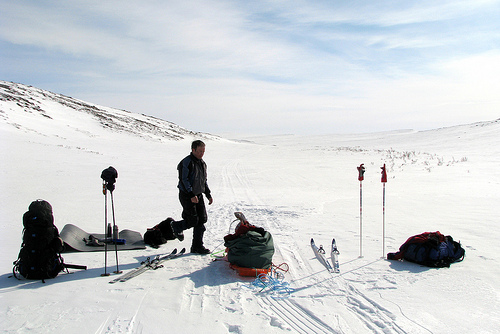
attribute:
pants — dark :
[146, 195, 208, 255]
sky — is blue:
[56, 6, 474, 143]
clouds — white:
[413, 31, 459, 47]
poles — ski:
[340, 162, 419, 262]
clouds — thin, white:
[0, 0, 498, 135]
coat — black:
[163, 155, 222, 200]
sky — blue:
[311, 37, 418, 74]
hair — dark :
[191, 137, 203, 155]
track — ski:
[206, 276, 255, 325]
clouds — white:
[299, 67, 395, 128]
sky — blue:
[24, 15, 481, 153]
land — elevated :
[1, 77, 226, 142]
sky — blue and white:
[182, 77, 402, 109]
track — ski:
[266, 303, 391, 327]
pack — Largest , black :
[12, 187, 74, 284]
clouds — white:
[306, 42, 393, 99]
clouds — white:
[217, 90, 496, 124]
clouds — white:
[170, 28, 245, 83]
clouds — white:
[148, 32, 305, 154]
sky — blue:
[351, 23, 480, 95]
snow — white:
[0, 69, 497, 330]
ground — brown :
[0, 76, 197, 148]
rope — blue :
[249, 270, 299, 297]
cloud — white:
[256, 4, 497, 56]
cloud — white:
[69, 0, 339, 78]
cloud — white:
[0, 1, 194, 81]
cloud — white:
[251, 13, 484, 56]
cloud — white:
[201, 0, 491, 27]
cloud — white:
[68, 52, 498, 145]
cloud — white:
[0, 2, 368, 82]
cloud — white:
[307, 17, 492, 68]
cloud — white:
[107, 1, 383, 96]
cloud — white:
[166, 56, 498, 157]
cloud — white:
[1, 1, 171, 79]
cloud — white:
[233, 0, 497, 54]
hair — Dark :
[188, 136, 202, 152]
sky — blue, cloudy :
[0, 3, 499, 142]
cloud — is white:
[133, 17, 247, 59]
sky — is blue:
[277, 19, 374, 30]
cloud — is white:
[132, 10, 243, 59]